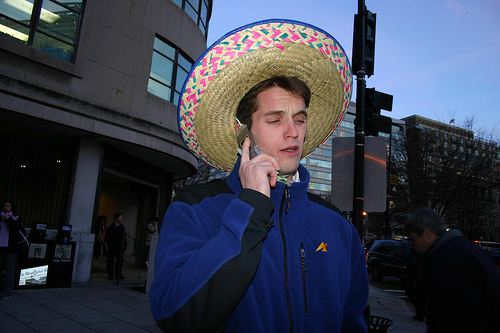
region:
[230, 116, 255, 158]
A cell phone next to a man's ear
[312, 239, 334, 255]
A yellow insignia on a man's jacket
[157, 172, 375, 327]
A multiple colored jacket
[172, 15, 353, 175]
A straw hat on a man's hat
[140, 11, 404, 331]
A man's wearing a hat and a jacket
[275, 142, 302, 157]
A man's mouth half open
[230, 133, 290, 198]
A man's hand holding a phone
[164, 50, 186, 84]
A window on a building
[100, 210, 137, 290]
A man in the background with a black jacket on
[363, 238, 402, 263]
A dark vehicle in the background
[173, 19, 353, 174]
multi colored straw hat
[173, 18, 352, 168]
straw hat on head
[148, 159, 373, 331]
blue and black jacket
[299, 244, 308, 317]
zipper pocket on jacket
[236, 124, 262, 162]
silver phone in hand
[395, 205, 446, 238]
grey cap on head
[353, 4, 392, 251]
stop light on pole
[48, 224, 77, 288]
black metal newspaper box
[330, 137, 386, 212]
sign hanging on post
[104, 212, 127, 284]
man walking on side walk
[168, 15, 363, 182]
Man wearing a multi colored straw hat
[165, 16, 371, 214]
Man in straw hat talking on a cell phone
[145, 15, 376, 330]
man wearing a straw hat and blue shirt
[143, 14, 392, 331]
Man wearing blue shirt with black stripes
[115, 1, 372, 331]
Man on cell phone in front of building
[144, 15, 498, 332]
Man on cell phone next to street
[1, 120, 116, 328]
newspaper racks in front of building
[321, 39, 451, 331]
back side of street sign on pole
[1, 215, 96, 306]
two newspaper racks on sidewalk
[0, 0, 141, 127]
Lights through office building window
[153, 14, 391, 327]
man wearing a sombrero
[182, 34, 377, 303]
man talking on a cell phone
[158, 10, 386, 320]
man wearing a blue jacket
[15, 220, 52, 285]
newspaper machine on the sidewalk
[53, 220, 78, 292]
newspaper machine on the sidewalk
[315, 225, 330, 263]
logo on the man's jacket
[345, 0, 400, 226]
traffic light behind the man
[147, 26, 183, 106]
window on a building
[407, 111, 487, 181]
building in the distance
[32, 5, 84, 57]
window on a building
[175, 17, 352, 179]
sombrero is worn by man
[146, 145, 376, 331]
fleece is worn by man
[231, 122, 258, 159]
telephone is held by man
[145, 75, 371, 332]
man wears sombrero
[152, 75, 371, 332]
man wears fleece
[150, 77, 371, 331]
man holds phone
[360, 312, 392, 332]
garbage bin is behind man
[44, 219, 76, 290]
newspaper bin is in distance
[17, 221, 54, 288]
newspaper bin is in distance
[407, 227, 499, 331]
jacket is worn by human